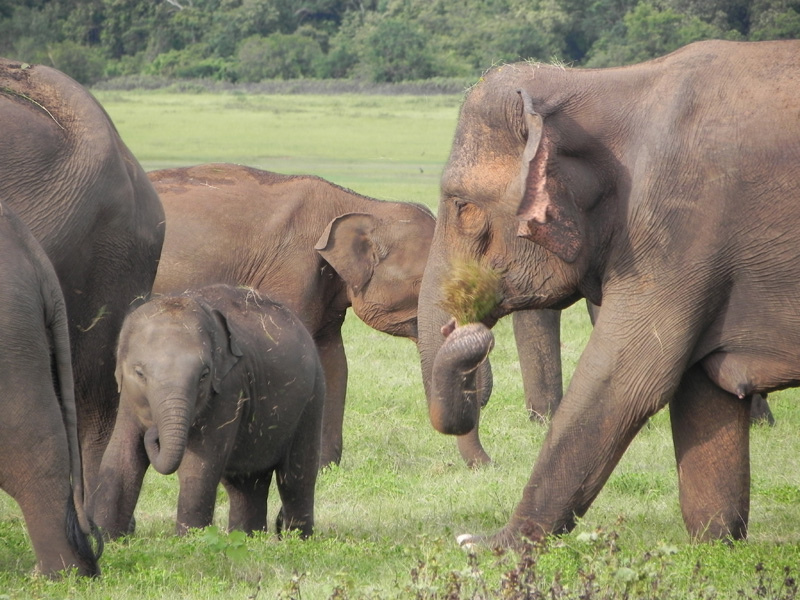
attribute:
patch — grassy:
[179, 533, 440, 597]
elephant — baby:
[74, 268, 344, 553]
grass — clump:
[441, 253, 487, 314]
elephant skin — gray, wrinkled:
[403, 18, 795, 567]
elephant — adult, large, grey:
[400, 18, 798, 579]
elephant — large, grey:
[132, 143, 446, 483]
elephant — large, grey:
[7, 38, 178, 596]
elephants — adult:
[1, 26, 798, 570]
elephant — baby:
[77, 276, 331, 542]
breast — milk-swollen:
[704, 350, 776, 399]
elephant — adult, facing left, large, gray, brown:
[413, 32, 776, 558]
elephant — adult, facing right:
[145, 161, 491, 472]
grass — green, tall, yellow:
[2, 87, 774, 596]